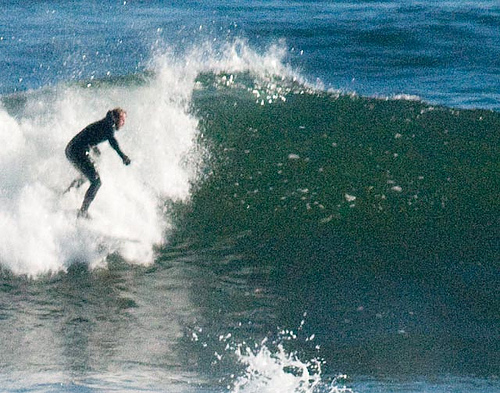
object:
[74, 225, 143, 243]
surfboard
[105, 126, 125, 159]
arm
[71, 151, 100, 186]
leg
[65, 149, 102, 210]
leg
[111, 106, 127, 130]
head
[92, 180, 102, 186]
knee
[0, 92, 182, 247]
water wall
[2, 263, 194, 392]
reflection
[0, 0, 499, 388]
surface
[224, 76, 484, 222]
dots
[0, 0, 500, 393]
ocean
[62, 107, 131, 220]
guy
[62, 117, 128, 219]
swimsuit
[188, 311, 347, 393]
splash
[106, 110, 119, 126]
hood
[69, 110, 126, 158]
jacket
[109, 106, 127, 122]
hair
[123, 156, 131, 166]
hand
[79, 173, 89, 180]
knee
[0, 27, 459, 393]
foam